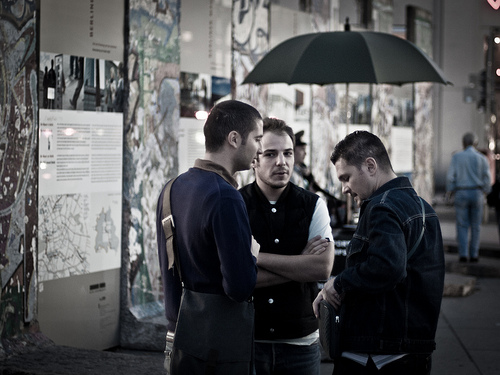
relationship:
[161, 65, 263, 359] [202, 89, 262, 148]
man has short hair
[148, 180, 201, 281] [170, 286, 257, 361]
strap attached to bag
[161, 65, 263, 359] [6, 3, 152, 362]
man standing near wall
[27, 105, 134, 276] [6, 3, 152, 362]
picture attached to wall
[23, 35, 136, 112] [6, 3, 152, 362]
picture attached to wall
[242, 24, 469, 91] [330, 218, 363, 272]
umbrella attached to table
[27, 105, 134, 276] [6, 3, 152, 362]
picture hanging on wall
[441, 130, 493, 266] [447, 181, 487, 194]
person wearing belt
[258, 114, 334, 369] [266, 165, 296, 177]
man has a mustache